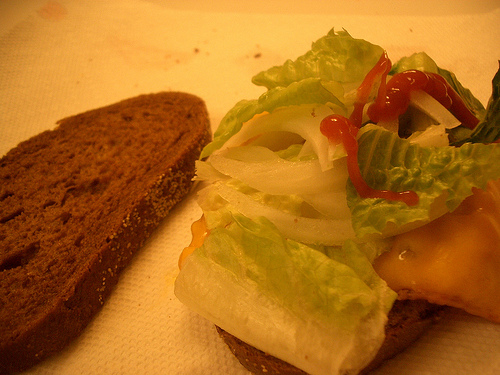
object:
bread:
[2, 90, 211, 371]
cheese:
[375, 194, 500, 321]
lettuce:
[183, 28, 483, 369]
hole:
[4, 240, 43, 272]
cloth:
[5, 7, 275, 117]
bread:
[214, 305, 439, 374]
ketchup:
[334, 62, 481, 202]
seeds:
[150, 190, 170, 219]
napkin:
[336, 4, 497, 67]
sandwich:
[4, 26, 500, 371]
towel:
[5, 3, 500, 86]